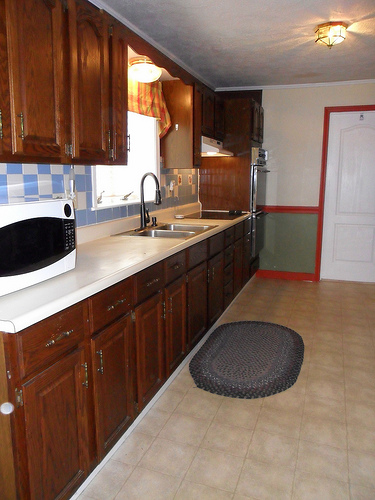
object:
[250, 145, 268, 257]
oven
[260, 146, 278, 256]
fridge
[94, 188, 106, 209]
handle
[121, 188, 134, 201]
handle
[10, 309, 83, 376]
drawer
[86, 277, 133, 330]
drawer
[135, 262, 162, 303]
drawer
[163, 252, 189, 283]
drawer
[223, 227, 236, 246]
drawer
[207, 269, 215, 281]
hardware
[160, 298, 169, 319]
hardware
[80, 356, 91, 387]
hardware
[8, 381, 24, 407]
hardware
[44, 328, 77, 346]
hardware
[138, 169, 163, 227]
faucet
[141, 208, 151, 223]
handle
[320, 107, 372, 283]
door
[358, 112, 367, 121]
hook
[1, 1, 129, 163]
cabinet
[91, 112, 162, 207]
window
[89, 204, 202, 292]
counter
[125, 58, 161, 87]
light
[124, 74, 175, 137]
curtains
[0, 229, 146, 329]
counter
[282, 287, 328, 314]
tile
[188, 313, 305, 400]
mat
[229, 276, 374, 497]
floor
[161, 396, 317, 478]
kitchen floor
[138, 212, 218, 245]
sink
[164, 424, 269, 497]
floor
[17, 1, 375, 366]
kitchen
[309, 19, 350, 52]
light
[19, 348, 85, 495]
cabinet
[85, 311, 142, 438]
cabinet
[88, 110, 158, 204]
light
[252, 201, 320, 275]
wall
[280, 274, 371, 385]
floor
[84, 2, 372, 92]
ceiling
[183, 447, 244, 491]
tile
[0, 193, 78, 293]
microwave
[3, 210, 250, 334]
counter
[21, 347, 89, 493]
cabinet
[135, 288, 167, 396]
cabinet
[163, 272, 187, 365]
cabinet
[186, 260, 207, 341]
cabinet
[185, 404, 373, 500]
pattern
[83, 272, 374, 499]
floor